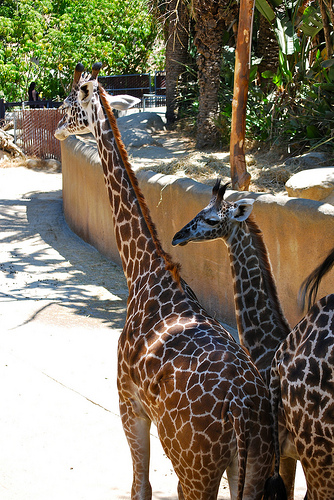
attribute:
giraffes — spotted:
[51, 65, 329, 359]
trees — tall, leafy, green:
[2, 2, 151, 91]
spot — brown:
[304, 356, 318, 386]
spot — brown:
[310, 328, 331, 358]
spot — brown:
[319, 358, 331, 392]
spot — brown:
[304, 384, 328, 419]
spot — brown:
[288, 380, 305, 407]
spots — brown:
[151, 316, 214, 385]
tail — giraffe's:
[254, 379, 296, 498]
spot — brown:
[256, 290, 269, 311]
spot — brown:
[239, 287, 259, 309]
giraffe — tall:
[26, 60, 333, 496]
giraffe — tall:
[170, 188, 298, 377]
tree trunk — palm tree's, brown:
[163, 0, 189, 129]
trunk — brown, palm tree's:
[191, 20, 223, 153]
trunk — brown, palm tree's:
[259, 16, 279, 102]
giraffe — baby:
[169, 176, 302, 382]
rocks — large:
[248, 103, 329, 187]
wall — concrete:
[105, 145, 316, 321]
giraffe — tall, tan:
[43, 65, 282, 498]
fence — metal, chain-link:
[17, 106, 60, 156]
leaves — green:
[20, 13, 32, 30]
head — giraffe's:
[51, 62, 103, 143]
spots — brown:
[157, 335, 195, 375]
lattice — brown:
[32, 114, 47, 149]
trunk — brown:
[229, 2, 258, 195]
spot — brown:
[143, 296, 161, 316]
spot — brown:
[147, 336, 164, 357]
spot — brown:
[184, 325, 200, 337]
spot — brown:
[172, 353, 192, 371]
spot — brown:
[161, 360, 174, 393]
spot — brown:
[260, 333, 281, 351]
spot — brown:
[255, 348, 276, 374]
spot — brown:
[259, 318, 277, 334]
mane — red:
[245, 213, 294, 337]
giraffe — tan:
[268, 292, 332, 499]